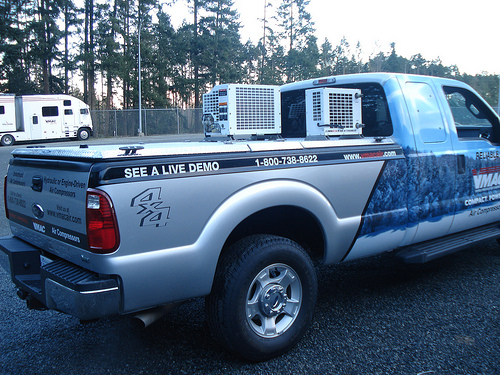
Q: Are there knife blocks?
A: No, there are no knife blocks.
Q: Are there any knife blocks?
A: No, there are no knife blocks.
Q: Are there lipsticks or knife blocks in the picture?
A: No, there are no knife blocks or lipsticks.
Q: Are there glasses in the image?
A: No, there are no glasses.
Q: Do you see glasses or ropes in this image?
A: No, there are no glasses or ropes.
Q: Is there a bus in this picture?
A: No, there are no buses.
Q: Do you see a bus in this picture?
A: No, there are no buses.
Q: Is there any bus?
A: No, there are no buses.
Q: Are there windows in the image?
A: Yes, there is a window.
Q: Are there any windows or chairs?
A: Yes, there is a window.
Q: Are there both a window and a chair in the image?
A: No, there is a window but no chairs.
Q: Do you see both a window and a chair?
A: No, there is a window but no chairs.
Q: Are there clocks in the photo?
A: No, there are no clocks.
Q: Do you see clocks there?
A: No, there are no clocks.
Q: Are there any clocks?
A: No, there are no clocks.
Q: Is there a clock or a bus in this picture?
A: No, there are no clocks or buses.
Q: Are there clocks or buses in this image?
A: No, there are no clocks or buses.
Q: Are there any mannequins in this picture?
A: No, there are no mannequins.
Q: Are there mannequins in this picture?
A: No, there are no mannequins.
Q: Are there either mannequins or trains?
A: No, there are no mannequins or trains.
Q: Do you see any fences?
A: Yes, there is a fence.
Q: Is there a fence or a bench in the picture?
A: Yes, there is a fence.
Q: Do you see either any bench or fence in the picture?
A: Yes, there is a fence.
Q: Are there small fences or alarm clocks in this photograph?
A: Yes, there is a small fence.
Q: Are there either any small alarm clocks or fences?
A: Yes, there is a small fence.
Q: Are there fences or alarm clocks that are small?
A: Yes, the fence is small.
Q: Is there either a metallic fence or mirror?
A: Yes, there is a metal fence.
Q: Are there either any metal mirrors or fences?
A: Yes, there is a metal fence.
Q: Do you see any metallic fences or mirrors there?
A: Yes, there is a metal fence.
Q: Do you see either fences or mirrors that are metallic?
A: Yes, the fence is metallic.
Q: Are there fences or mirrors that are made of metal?
A: Yes, the fence is made of metal.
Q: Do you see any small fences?
A: Yes, there is a small fence.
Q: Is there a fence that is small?
A: Yes, there is a fence that is small.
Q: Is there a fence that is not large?
A: Yes, there is a small fence.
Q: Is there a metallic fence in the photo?
A: Yes, there is a metal fence.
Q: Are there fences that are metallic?
A: Yes, there is a fence that is metallic.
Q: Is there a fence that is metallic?
A: Yes, there is a fence that is metallic.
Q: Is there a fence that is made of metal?
A: Yes, there is a fence that is made of metal.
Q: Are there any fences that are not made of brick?
A: Yes, there is a fence that is made of metal.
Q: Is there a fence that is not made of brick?
A: Yes, there is a fence that is made of metal.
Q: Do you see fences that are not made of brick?
A: Yes, there is a fence that is made of metal.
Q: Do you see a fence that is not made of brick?
A: Yes, there is a fence that is made of metal.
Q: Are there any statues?
A: No, there are no statues.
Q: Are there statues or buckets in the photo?
A: No, there are no statues or buckets.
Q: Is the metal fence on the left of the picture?
A: Yes, the fence is on the left of the image.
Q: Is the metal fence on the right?
A: No, the fence is on the left of the image.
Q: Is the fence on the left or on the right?
A: The fence is on the left of the image.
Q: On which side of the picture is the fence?
A: The fence is on the left of the image.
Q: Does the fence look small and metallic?
A: Yes, the fence is small and metallic.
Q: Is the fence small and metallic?
A: Yes, the fence is small and metallic.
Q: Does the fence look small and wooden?
A: No, the fence is small but metallic.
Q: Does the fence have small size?
A: Yes, the fence is small.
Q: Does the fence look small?
A: Yes, the fence is small.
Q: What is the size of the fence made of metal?
A: The fence is small.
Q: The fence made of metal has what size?
A: The fence is small.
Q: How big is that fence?
A: The fence is small.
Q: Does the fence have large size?
A: No, the fence is small.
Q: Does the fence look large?
A: No, the fence is small.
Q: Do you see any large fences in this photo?
A: No, there is a fence but it is small.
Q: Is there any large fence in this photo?
A: No, there is a fence but it is small.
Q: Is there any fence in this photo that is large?
A: No, there is a fence but it is small.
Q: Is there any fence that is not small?
A: No, there is a fence but it is small.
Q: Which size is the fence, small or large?
A: The fence is small.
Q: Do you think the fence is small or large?
A: The fence is small.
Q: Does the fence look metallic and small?
A: Yes, the fence is metallic and small.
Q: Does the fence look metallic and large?
A: No, the fence is metallic but small.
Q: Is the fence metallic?
A: Yes, the fence is metallic.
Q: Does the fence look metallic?
A: Yes, the fence is metallic.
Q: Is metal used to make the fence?
A: Yes, the fence is made of metal.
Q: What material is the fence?
A: The fence is made of metal.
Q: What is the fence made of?
A: The fence is made of metal.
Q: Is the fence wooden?
A: No, the fence is metallic.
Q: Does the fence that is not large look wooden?
A: No, the fence is metallic.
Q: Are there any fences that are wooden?
A: No, there is a fence but it is metallic.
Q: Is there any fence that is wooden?
A: No, there is a fence but it is metallic.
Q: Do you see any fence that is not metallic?
A: No, there is a fence but it is metallic.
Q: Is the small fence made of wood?
A: No, the fence is made of metal.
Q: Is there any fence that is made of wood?
A: No, there is a fence but it is made of metal.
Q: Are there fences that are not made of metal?
A: No, there is a fence but it is made of metal.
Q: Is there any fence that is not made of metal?
A: No, there is a fence but it is made of metal.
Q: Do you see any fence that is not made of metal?
A: No, there is a fence but it is made of metal.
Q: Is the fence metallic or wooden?
A: The fence is metallic.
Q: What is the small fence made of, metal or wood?
A: The fence is made of metal.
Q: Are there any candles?
A: No, there are no candles.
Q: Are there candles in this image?
A: No, there are no candles.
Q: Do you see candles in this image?
A: No, there are no candles.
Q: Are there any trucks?
A: Yes, there is a truck.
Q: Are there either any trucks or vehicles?
A: Yes, there is a truck.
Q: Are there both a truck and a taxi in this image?
A: No, there is a truck but no taxis.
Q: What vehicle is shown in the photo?
A: The vehicle is a truck.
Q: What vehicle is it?
A: The vehicle is a truck.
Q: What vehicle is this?
A: That is a truck.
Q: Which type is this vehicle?
A: That is a truck.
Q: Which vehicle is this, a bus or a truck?
A: That is a truck.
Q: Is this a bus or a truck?
A: This is a truck.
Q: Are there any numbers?
A: Yes, there are numbers.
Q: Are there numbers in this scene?
A: Yes, there are numbers.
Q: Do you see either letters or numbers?
A: Yes, there are numbers.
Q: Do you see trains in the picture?
A: No, there are no trains.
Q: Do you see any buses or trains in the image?
A: No, there are no trains or buses.